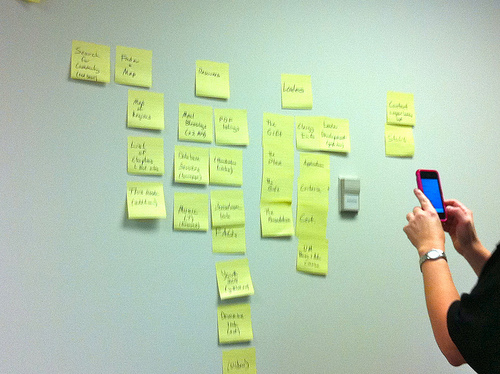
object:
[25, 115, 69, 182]
wall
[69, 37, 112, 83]
sticker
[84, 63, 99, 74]
writing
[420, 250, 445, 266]
watch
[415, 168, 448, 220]
cellphone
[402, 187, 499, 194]
man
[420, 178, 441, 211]
picture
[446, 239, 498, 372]
shirt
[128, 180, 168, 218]
paper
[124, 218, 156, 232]
shadow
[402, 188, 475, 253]
hands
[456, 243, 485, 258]
wrist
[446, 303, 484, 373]
sleeve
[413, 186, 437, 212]
finger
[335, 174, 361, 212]
box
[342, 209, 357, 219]
shadow